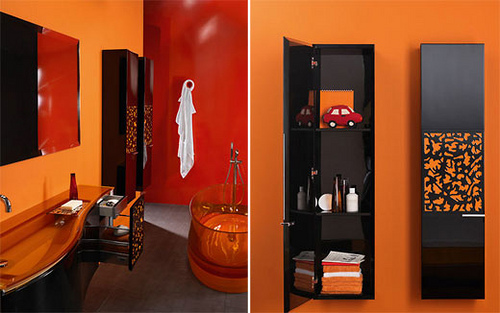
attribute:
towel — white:
[175, 81, 197, 179]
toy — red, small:
[322, 104, 364, 129]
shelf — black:
[314, 127, 371, 132]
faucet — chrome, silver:
[0, 194, 12, 213]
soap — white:
[62, 199, 84, 211]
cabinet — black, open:
[281, 35, 376, 312]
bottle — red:
[68, 172, 78, 202]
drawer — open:
[97, 194, 129, 220]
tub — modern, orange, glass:
[187, 182, 248, 294]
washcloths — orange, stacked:
[321, 266, 364, 295]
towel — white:
[323, 269, 362, 277]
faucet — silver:
[224, 142, 245, 206]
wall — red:
[143, 1, 248, 212]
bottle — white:
[346, 187, 359, 212]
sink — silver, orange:
[1, 195, 93, 279]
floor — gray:
[69, 202, 246, 312]